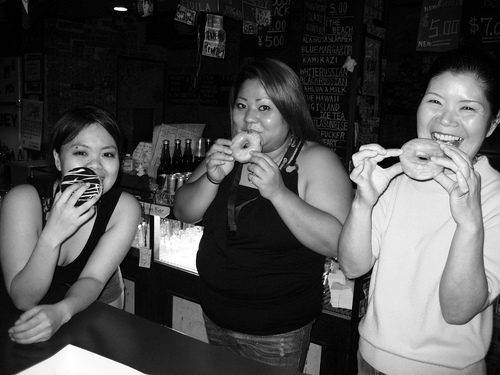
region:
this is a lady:
[204, 73, 311, 333]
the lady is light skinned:
[303, 160, 340, 202]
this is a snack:
[233, 129, 263, 157]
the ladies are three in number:
[44, 88, 436, 364]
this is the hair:
[281, 78, 314, 127]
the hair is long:
[288, 98, 315, 129]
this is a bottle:
[158, 132, 183, 169]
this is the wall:
[316, 17, 371, 102]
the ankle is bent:
[340, 235, 371, 291]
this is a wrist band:
[201, 170, 223, 191]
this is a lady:
[338, 58, 488, 373]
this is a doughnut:
[385, 138, 462, 181]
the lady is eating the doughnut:
[233, 125, 266, 155]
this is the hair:
[268, 70, 298, 102]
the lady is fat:
[193, 134, 330, 331]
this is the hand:
[273, 191, 325, 250]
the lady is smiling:
[428, 130, 462, 142]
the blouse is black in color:
[207, 238, 287, 307]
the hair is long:
[275, 73, 304, 100]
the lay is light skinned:
[445, 80, 462, 95]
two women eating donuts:
[190, 54, 486, 184]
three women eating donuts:
[23, 48, 485, 229]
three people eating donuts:
[0, 46, 482, 242]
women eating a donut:
[25, 103, 127, 216]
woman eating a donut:
[194, 55, 318, 179]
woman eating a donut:
[382, 72, 490, 177]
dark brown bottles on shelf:
[152, 137, 177, 183]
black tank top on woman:
[194, 142, 314, 325]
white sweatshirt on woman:
[357, 165, 495, 374]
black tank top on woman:
[3, 183, 117, 320]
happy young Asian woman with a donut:
[3, 100, 156, 347]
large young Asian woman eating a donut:
[170, 54, 354, 367]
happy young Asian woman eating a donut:
[340, 56, 498, 360]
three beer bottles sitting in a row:
[155, 133, 197, 207]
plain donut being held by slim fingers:
[391, 135, 449, 189]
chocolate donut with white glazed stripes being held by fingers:
[58, 163, 107, 210]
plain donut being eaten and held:
[227, 125, 268, 168]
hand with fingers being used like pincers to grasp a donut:
[343, 138, 412, 204]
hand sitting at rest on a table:
[5, 303, 70, 350]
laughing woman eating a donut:
[332, 58, 493, 373]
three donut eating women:
[23, 59, 490, 348]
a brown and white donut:
[47, 150, 129, 221]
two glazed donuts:
[203, 123, 493, 252]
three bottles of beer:
[138, 124, 204, 209]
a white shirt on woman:
[338, 137, 492, 374]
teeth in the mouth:
[429, 125, 476, 153]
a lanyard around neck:
[183, 110, 305, 227]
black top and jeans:
[184, 124, 334, 374]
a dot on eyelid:
[68, 139, 87, 153]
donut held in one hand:
[38, 158, 139, 278]